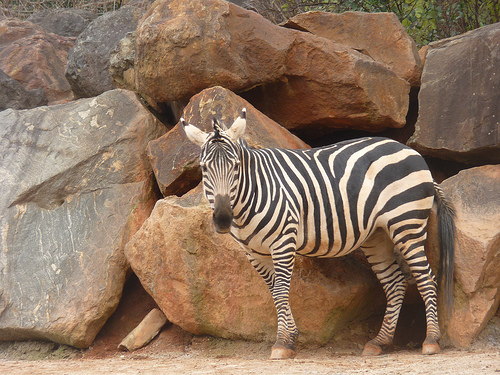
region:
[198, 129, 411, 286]
a zebra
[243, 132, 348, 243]
a zebra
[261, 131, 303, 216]
a zebra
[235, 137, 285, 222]
a zebra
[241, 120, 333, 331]
a zebra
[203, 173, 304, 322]
a zebra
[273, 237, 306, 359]
a zebra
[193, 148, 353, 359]
a zebra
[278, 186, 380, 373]
a zebra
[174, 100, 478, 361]
a zebra looking at the camera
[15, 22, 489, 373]
a animal next to rocks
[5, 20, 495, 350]
scene at the zoo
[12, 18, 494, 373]
scene that is outdoors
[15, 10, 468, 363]
scene that is during the day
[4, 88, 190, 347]
a big gray boulder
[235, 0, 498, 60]
trees seen from the background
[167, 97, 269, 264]
head of a zebra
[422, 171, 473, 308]
tail of a zebra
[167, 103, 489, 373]
a zebra that is white and black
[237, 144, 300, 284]
a zebra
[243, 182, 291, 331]
a zebra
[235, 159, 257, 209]
a zebra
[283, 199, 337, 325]
a zebra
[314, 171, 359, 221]
part of a stomach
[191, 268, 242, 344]
part of a stone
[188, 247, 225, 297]
part of a stone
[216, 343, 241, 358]
part of a ground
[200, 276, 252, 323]
pat of a stone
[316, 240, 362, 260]
edge of a tummy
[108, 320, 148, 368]
part of a stone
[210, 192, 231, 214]
part of a zebra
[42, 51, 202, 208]
hard rocks are visible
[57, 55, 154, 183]
hard rocks are visible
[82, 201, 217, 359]
hard rocks are visible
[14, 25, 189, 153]
hard rocks are visible